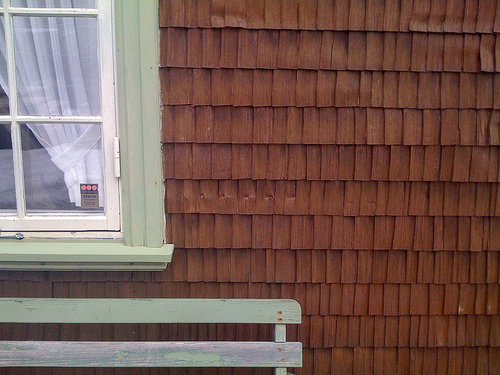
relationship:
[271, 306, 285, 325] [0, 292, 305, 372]
holes in bench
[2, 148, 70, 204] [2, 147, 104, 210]
spread on bed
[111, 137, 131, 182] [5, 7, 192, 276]
hinge on window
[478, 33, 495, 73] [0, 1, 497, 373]
shingle on wall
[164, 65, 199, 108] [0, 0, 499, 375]
block on brown wall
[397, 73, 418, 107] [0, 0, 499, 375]
block on brown wall